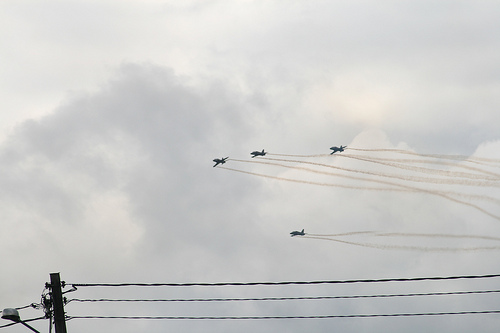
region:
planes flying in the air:
[87, 80, 383, 330]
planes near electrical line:
[122, 90, 379, 324]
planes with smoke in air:
[146, 79, 498, 291]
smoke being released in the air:
[101, 90, 489, 288]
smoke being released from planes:
[118, 110, 403, 331]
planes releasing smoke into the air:
[132, 63, 428, 331]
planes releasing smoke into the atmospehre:
[47, 69, 448, 332]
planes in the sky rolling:
[53, 68, 432, 273]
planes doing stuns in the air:
[110, 81, 429, 329]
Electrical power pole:
[46, 266, 71, 331]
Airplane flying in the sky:
[210, 136, 347, 241]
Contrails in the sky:
[314, 152, 498, 253]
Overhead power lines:
[67, 271, 497, 318]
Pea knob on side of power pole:
[41, 279, 52, 290]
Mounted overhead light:
[0, 307, 43, 331]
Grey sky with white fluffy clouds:
[1, 2, 498, 137]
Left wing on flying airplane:
[210, 162, 220, 172]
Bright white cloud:
[308, 71, 398, 126]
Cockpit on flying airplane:
[249, 149, 257, 156]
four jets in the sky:
[207, 138, 498, 255]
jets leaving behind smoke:
[209, 142, 499, 259]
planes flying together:
[209, 135, 499, 246]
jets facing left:
[209, 144, 497, 262]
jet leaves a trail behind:
[287, 227, 499, 262]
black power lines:
[2, 265, 498, 331]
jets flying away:
[211, 137, 497, 254]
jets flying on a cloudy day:
[211, 140, 499, 257]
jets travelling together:
[206, 137, 499, 246]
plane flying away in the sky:
[282, 225, 499, 257]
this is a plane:
[206, 148, 242, 182]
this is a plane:
[277, 223, 314, 243]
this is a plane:
[210, 140, 235, 173]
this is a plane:
[234, 133, 286, 171]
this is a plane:
[314, 130, 359, 162]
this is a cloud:
[99, 143, 154, 190]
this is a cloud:
[106, 103, 188, 193]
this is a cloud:
[285, 43, 372, 108]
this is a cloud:
[69, 214, 199, 276]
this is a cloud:
[44, 90, 141, 154]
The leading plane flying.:
[201, 151, 234, 176]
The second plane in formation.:
[243, 143, 275, 164]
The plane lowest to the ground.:
[282, 223, 328, 254]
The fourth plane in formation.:
[326, 138, 356, 162]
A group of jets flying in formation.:
[196, 139, 363, 251]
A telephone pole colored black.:
[45, 269, 70, 330]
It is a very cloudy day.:
[5, 8, 494, 328]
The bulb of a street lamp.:
[5, 305, 25, 322]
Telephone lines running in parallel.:
[87, 280, 487, 316]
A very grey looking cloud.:
[20, 59, 256, 254]